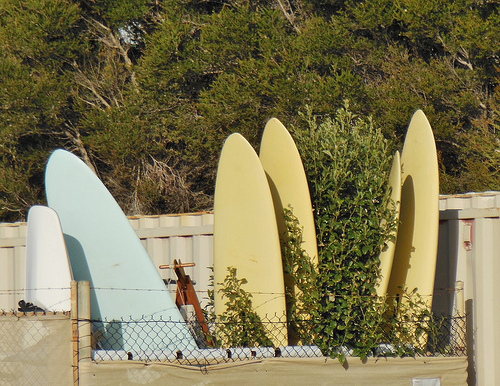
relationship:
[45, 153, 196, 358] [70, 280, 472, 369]
surfboard in planter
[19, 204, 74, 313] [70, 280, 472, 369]
surfboard sticking out of planter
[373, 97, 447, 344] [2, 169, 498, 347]
surfboards next to wall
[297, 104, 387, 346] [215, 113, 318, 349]
bush beside surfboards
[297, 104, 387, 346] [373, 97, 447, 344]
bush beside surfboards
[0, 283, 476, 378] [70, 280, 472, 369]
fence in front of planter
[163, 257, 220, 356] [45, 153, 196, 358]
pulley beside surfboard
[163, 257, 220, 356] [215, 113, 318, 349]
pulley beside surfboards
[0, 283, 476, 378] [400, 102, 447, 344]
fence in front of surfboards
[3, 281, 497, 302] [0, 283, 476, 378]
barbed wire on fence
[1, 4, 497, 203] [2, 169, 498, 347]
trees behind wall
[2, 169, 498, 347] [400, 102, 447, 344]
wall behind surfboards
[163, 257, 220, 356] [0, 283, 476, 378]
pulley behind fence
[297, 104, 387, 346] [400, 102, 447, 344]
bush with surfboards